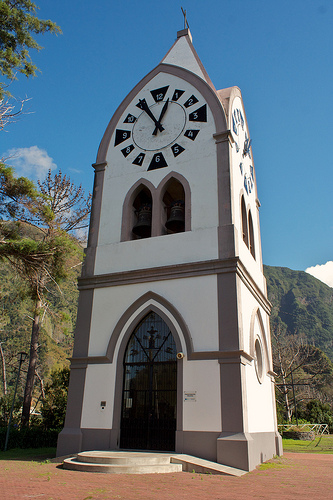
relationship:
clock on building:
[113, 82, 208, 173] [63, 19, 278, 460]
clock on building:
[113, 82, 208, 173] [51, 29, 285, 480]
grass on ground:
[0, 431, 331, 461] [0, 433, 331, 499]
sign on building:
[182, 390, 197, 402] [63, 19, 278, 460]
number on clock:
[153, 91, 166, 102] [112, 77, 209, 181]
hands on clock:
[133, 95, 175, 135] [113, 82, 208, 173]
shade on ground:
[7, 443, 53, 462] [5, 472, 330, 498]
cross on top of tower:
[160, 7, 241, 56] [76, 40, 271, 425]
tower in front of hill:
[59, 2, 218, 242] [263, 263, 333, 352]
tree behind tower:
[271, 327, 306, 423] [53, 27, 285, 475]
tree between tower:
[271, 327, 306, 423] [53, 27, 285, 475]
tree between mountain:
[0, 174, 95, 453] [262, 263, 331, 429]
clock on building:
[104, 76, 238, 195] [63, 19, 278, 460]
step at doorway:
[61, 448, 183, 476] [117, 303, 180, 454]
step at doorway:
[61, 455, 185, 475] [117, 303, 180, 454]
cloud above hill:
[303, 258, 331, 285] [264, 262, 323, 352]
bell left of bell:
[132, 197, 151, 237] [158, 193, 187, 229]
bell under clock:
[159, 199, 188, 232] [113, 82, 208, 173]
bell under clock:
[126, 201, 153, 237] [113, 82, 208, 173]